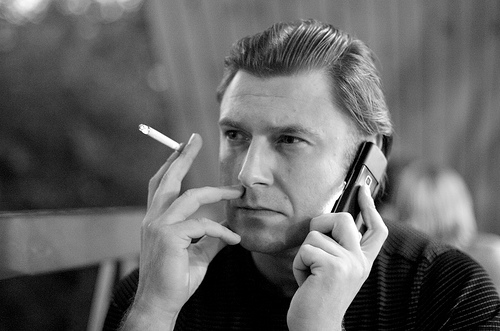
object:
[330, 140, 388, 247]
phone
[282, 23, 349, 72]
marks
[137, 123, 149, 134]
ash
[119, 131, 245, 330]
hand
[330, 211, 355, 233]
knuckle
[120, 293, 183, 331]
wrist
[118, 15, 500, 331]
man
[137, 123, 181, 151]
cigarrate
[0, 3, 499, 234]
background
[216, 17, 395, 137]
hair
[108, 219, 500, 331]
shirt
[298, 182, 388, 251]
finger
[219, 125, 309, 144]
eye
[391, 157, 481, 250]
woman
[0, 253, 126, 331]
chair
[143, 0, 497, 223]
curtain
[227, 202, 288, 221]
mouth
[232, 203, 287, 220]
lip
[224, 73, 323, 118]
fore head